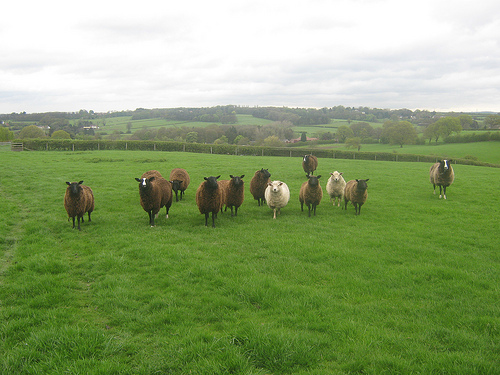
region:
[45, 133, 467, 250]
man sheep standing in a field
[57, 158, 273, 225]
several brown sheep standing in a field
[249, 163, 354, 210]
two white sheep in the flock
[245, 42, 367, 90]
cloudy white skies over the field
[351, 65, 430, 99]
fluffy white clouds in the sky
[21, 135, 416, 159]
hedges growing along the fence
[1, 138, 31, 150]
brown wooden fence surrounding the field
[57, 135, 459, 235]
a herd of sheep walking together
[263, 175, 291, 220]
a white sheep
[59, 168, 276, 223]
a group of brown sheep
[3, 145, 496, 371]
green is very healthy and green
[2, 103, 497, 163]
trees in background behind field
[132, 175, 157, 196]
brown sheep has a white face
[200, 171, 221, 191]
brown sheep has a black face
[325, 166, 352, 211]
second white sheep among a herd of brown sheep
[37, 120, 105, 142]
house far off in the distance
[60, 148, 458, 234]
herd of sheep walking in field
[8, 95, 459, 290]
the sheep are standing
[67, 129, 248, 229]
the sheep are brown in colour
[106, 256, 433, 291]
the grass is bright green in colour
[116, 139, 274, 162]
the hedge is neatly kept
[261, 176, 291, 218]
the sheep is white in colour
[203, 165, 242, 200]
the heads are black in colour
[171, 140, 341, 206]
the ears are all raised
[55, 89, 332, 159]
the landscape is hilly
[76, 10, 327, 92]
the sky is cloudy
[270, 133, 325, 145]
the house has a red roof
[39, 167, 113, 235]
this is a sheep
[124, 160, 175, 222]
this is a sheep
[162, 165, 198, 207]
this is a sheep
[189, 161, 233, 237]
this is a sheep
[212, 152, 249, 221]
this is a sheep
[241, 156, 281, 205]
this is a sheep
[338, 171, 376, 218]
this is a sheep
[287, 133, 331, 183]
this is a sheep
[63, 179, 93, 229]
black sheep standing by itself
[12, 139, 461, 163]
dark green shrubs along pasture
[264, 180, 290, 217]
solid white sheep in the middle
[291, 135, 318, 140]
red roof of a building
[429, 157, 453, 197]
sheep with white stripe on its face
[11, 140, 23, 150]
brown wooden gate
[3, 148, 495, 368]
green grassy pasture area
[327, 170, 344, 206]
solid white sheep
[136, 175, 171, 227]
sheep with white stripe on face and white hooves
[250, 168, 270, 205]
solid black sheep looking to the side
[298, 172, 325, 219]
A sheep in a field of grass.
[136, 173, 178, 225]
A sheep in a field of grass.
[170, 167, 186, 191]
A sheep in a field of grass.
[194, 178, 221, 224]
A sheep in a field of grass.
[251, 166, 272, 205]
A sheep in a field of grass.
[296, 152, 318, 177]
A sheep in a field of grass.